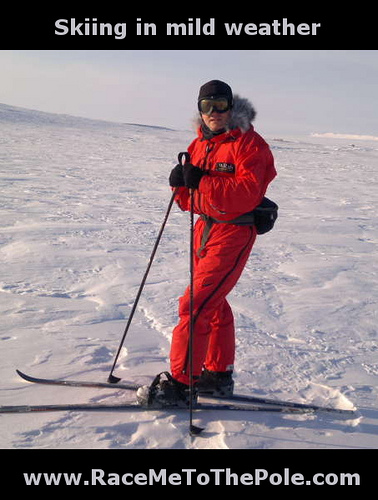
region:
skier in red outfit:
[156, 59, 260, 421]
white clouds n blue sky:
[320, 69, 348, 87]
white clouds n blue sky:
[308, 79, 345, 107]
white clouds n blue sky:
[348, 94, 376, 123]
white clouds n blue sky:
[280, 48, 299, 72]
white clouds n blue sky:
[19, 67, 47, 97]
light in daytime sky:
[0, 50, 376, 134]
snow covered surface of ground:
[1, 103, 377, 447]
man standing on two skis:
[1, 79, 352, 412]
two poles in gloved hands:
[107, 149, 202, 435]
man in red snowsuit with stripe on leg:
[137, 78, 276, 409]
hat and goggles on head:
[197, 78, 234, 130]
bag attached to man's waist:
[168, 79, 279, 233]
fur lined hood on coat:
[173, 95, 277, 221]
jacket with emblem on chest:
[171, 126, 276, 222]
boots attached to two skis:
[1, 370, 351, 415]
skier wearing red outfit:
[133, 68, 269, 408]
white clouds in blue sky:
[320, 59, 358, 78]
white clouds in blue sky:
[327, 91, 360, 115]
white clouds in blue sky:
[274, 50, 292, 74]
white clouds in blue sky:
[277, 80, 299, 105]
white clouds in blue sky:
[50, 63, 86, 86]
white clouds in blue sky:
[84, 50, 160, 101]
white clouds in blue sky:
[102, 69, 154, 103]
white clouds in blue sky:
[54, 67, 81, 95]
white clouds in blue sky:
[108, 74, 132, 89]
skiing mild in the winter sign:
[47, 6, 321, 46]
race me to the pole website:
[24, 458, 364, 499]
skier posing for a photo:
[17, 72, 313, 404]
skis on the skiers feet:
[6, 341, 362, 430]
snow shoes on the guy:
[137, 360, 201, 408]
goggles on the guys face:
[191, 96, 233, 114]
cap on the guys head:
[195, 73, 252, 101]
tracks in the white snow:
[267, 257, 356, 378]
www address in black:
[9, 452, 371, 498]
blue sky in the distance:
[31, 60, 145, 105]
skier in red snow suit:
[0, 80, 355, 433]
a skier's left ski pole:
[185, 190, 202, 433]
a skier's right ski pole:
[108, 183, 179, 381]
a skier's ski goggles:
[198, 95, 230, 113]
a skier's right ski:
[16, 369, 356, 415]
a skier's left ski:
[1, 404, 314, 421]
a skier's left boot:
[135, 378, 199, 406]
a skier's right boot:
[195, 369, 234, 396]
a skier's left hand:
[183, 164, 206, 189]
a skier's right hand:
[170, 161, 185, 188]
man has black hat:
[165, 82, 242, 123]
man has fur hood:
[196, 111, 258, 136]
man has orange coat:
[193, 129, 271, 219]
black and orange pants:
[157, 215, 270, 371]